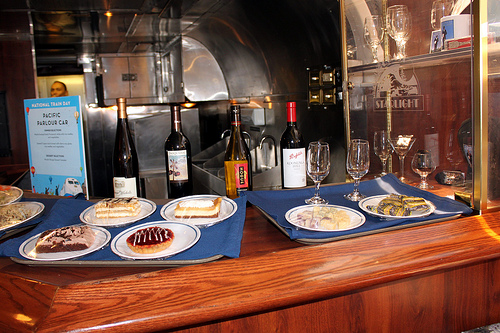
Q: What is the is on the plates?
A: Food.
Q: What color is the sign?
A: Blue.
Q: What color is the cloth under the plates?
A: Blue.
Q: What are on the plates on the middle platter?
A: Pastries.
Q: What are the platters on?
A: Counter.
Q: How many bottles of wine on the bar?
A: Four.